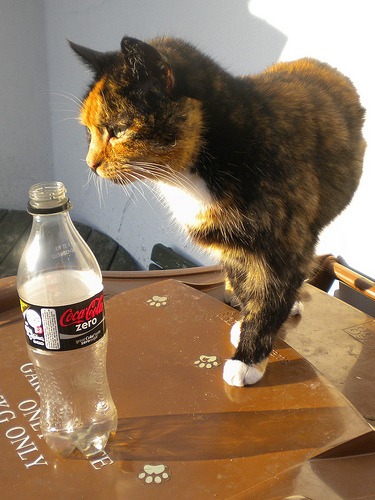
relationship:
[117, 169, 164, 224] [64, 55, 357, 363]
whiskers on cat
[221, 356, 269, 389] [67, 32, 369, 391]
paw on cat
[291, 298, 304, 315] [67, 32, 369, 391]
white paw on cat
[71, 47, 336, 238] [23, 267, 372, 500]
cat on cart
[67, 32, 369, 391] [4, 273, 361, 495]
cat on table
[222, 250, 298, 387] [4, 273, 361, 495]
leg on table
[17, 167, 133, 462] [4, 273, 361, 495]
bottle on table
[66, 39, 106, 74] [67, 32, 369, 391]
ear standing out on cat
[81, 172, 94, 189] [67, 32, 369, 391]
white whiskers of cat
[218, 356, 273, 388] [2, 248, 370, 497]
paw on top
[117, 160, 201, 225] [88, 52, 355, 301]
whiskers on cat